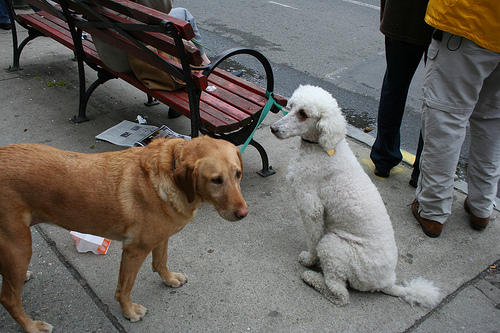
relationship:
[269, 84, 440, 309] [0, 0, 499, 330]
poodle sitting on sidewalk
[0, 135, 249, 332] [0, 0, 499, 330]
retriever standing on sidewalk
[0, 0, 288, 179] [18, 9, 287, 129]
bench has seat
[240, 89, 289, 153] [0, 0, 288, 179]
leash attached to bench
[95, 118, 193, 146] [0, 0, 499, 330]
magazine laying on sidewalk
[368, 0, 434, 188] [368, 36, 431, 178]
person wearing jeans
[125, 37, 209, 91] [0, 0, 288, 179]
bag on top of bench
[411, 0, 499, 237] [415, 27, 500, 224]
man wearing pants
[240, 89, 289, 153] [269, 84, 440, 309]
leash holding down poodle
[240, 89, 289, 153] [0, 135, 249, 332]
leash holding down retriever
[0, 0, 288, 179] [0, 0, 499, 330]
bench sitting on sidewalk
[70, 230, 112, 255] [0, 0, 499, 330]
paper laying on sidewalk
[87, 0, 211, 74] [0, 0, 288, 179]
person sitting on bench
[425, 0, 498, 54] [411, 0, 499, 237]
windbreaker worn by man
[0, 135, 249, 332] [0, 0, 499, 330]
retriever on top of sidewalk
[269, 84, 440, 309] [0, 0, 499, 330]
poodle on top of sidewalk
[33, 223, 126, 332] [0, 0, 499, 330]
crack in middle of sidewalk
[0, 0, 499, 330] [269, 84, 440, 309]
sidewalk with poodle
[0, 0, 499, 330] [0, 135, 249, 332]
sidewalk with retriever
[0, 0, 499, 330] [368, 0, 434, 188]
sidewalk with person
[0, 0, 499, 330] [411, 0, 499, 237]
sidewalk with man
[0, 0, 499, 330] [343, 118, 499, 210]
sidewalk has curb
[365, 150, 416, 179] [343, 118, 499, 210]
streak on top of curb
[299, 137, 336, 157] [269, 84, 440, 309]
collar worn on poodle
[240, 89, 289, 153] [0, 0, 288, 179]
leash tied to bench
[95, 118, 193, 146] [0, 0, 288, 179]
magazine under bench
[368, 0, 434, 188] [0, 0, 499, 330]
person standing on sidewalk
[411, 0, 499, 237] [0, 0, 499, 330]
man standing on sidewalk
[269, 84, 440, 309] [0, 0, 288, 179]
poodle tied to bench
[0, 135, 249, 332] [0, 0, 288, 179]
retriever tied to bench